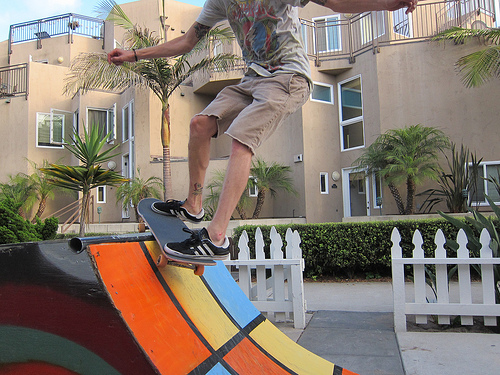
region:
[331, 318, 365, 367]
There is a dark patch of sidewalk here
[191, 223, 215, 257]
There are black shoes visible here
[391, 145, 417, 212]
There are green palm trees visible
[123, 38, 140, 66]
This boy is wearing a bracelet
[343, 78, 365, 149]
There is a large window in the distance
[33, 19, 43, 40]
There is a black gate that is on top of the house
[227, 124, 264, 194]
This boy is wearing khaki-colored shorts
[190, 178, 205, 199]
a tattoo on a man's leg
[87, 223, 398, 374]
a multicolored skate ramp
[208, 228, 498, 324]
short small white picket fence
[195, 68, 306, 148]
cargo shorts on a man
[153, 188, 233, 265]
white and black shoes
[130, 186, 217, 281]
a skateboard with orange wheels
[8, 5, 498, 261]
palm trees by the houses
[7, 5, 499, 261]
row of houses off of the street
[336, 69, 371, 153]
large window on the house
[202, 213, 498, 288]
bushes lining the sidewalk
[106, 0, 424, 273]
A man is skateboarding.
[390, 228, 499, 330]
A white picket fence is on the sidewalk.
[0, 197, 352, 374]
The skateboard is on a jump.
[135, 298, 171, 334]
The jump is orange.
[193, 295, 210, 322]
The jump is yellow.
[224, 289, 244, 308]
The jump is blue.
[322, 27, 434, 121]
A building is behind the skateboarder.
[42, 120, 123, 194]
Palm trees are in front of the building.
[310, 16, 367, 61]
The building has a balcony.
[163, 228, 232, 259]
The sneakers are black and white.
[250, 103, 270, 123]
man wearing tan shorts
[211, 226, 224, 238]
man wearing no socks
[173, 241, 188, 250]
top of black sneakers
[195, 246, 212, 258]
white stripes on sneakers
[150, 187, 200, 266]
man wearing black sneakers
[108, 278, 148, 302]
orange color on ramp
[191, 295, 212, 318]
yellow color on ramp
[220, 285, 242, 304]
blue color on ramp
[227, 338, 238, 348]
black line on ramp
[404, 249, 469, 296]
pickett white fence around building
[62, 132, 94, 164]
green leaf on tree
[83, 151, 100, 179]
green leaf on tree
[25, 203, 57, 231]
green leaf on tree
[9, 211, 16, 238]
green leaf on tree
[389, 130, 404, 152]
green leaf on tree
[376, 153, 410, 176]
green leaf on tree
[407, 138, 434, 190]
green leaf on tree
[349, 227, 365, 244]
green leaf on tree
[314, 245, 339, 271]
green leaf on tree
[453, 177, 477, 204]
green leaf on tree